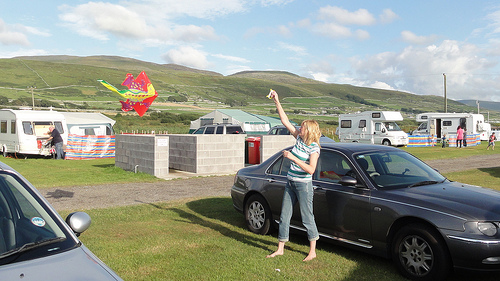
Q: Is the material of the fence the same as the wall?
A: No, the fence is made of plastic and the wall is made of concrete.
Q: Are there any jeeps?
A: No, there are no jeeps.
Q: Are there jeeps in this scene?
A: No, there are no jeeps.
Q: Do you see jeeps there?
A: No, there are no jeeps.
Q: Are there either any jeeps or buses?
A: No, there are no jeeps or buses.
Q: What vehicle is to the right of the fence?
A: The vehicle is a car.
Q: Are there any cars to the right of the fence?
A: Yes, there is a car to the right of the fence.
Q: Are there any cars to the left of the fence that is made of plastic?
A: No, the car is to the right of the fence.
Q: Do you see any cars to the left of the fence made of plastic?
A: No, the car is to the right of the fence.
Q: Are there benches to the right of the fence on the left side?
A: No, there is a car to the right of the fence.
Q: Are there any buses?
A: No, there are no buses.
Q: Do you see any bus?
A: No, there are no buses.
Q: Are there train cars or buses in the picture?
A: No, there are no buses or train cars.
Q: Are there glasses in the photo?
A: No, there are no glasses.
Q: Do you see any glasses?
A: No, there are no glasses.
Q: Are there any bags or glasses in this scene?
A: No, there are no glasses or bags.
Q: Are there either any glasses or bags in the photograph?
A: No, there are no glasses or bags.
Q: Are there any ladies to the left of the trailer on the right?
A: Yes, there is a lady to the left of the trailer.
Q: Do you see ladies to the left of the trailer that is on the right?
A: Yes, there is a lady to the left of the trailer.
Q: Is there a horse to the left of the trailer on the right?
A: No, there is a lady to the left of the trailer.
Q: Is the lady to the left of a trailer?
A: Yes, the lady is to the left of a trailer.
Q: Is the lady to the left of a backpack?
A: No, the lady is to the left of a trailer.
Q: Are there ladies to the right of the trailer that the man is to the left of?
A: Yes, there is a lady to the right of the trailer.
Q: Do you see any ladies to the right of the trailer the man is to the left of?
A: Yes, there is a lady to the right of the trailer.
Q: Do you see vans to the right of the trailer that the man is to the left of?
A: No, there is a lady to the right of the trailer.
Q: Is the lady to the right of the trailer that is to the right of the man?
A: Yes, the lady is to the right of the trailer.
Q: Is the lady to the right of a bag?
A: No, the lady is to the right of the trailer.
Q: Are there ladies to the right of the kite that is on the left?
A: Yes, there is a lady to the right of the kite.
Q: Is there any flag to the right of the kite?
A: No, there is a lady to the right of the kite.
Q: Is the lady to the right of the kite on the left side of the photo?
A: Yes, the lady is to the right of the kite.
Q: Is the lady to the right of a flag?
A: No, the lady is to the right of the kite.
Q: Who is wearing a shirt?
A: The lady is wearing a shirt.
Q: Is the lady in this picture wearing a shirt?
A: Yes, the lady is wearing a shirt.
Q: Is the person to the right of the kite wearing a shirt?
A: Yes, the lady is wearing a shirt.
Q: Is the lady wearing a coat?
A: No, the lady is wearing a shirt.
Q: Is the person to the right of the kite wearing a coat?
A: No, the lady is wearing a shirt.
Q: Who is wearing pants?
A: The lady is wearing pants.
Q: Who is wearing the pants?
A: The lady is wearing pants.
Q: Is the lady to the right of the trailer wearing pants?
A: Yes, the lady is wearing pants.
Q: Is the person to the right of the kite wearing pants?
A: Yes, the lady is wearing pants.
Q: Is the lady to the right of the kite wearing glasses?
A: No, the lady is wearing pants.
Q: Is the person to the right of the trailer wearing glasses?
A: No, the lady is wearing pants.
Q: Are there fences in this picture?
A: Yes, there is a fence.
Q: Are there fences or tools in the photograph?
A: Yes, there is a fence.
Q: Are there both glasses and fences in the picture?
A: No, there is a fence but no glasses.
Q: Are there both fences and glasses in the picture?
A: No, there is a fence but no glasses.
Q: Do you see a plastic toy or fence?
A: Yes, there is a plastic fence.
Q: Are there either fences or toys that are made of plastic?
A: Yes, the fence is made of plastic.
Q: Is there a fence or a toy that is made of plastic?
A: Yes, the fence is made of plastic.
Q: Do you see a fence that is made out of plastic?
A: Yes, there is a fence that is made of plastic.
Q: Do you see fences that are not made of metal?
A: Yes, there is a fence that is made of plastic.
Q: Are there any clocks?
A: No, there are no clocks.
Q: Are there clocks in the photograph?
A: No, there are no clocks.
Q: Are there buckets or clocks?
A: No, there are no clocks or buckets.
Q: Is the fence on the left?
A: Yes, the fence is on the left of the image.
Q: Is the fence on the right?
A: No, the fence is on the left of the image.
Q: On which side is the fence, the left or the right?
A: The fence is on the left of the image.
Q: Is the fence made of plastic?
A: Yes, the fence is made of plastic.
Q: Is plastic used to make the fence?
A: Yes, the fence is made of plastic.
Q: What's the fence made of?
A: The fence is made of plastic.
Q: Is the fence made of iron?
A: No, the fence is made of plastic.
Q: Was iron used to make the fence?
A: No, the fence is made of plastic.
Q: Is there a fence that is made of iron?
A: No, there is a fence but it is made of plastic.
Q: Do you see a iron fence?
A: No, there is a fence but it is made of plastic.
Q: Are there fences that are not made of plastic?
A: No, there is a fence but it is made of plastic.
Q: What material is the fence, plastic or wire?
A: The fence is made of plastic.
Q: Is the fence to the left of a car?
A: Yes, the fence is to the left of a car.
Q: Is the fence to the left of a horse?
A: No, the fence is to the left of a car.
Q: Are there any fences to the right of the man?
A: Yes, there is a fence to the right of the man.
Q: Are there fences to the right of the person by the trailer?
A: Yes, there is a fence to the right of the man.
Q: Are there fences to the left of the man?
A: No, the fence is to the right of the man.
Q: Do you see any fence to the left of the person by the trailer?
A: No, the fence is to the right of the man.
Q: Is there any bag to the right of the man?
A: No, there is a fence to the right of the man.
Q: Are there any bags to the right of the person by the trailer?
A: No, there is a fence to the right of the man.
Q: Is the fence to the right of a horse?
A: No, the fence is to the right of the man.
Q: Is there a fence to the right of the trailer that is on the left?
A: Yes, there is a fence to the right of the trailer.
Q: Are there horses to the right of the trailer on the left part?
A: No, there is a fence to the right of the trailer.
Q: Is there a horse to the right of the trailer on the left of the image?
A: No, there is a fence to the right of the trailer.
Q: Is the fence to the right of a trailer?
A: Yes, the fence is to the right of a trailer.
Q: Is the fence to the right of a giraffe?
A: No, the fence is to the right of a trailer.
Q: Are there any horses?
A: No, there are no horses.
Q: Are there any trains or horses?
A: No, there are no horses or trains.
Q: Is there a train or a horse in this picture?
A: No, there are no horses or trains.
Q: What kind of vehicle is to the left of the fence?
A: The vehicle is a trailer.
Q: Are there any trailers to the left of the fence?
A: Yes, there is a trailer to the left of the fence.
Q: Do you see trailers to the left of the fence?
A: Yes, there is a trailer to the left of the fence.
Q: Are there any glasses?
A: No, there are no glasses.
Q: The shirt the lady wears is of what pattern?
A: The shirt is striped.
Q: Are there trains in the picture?
A: No, there are no trains.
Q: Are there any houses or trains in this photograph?
A: No, there are no trains or houses.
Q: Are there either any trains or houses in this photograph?
A: No, there are no trains or houses.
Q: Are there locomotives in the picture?
A: No, there are no locomotives.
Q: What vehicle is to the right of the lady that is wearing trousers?
A: The vehicle is a trailer.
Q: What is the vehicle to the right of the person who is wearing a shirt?
A: The vehicle is a trailer.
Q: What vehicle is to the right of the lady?
A: The vehicle is a trailer.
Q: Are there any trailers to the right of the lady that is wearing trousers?
A: Yes, there is a trailer to the right of the lady.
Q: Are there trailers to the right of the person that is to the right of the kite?
A: Yes, there is a trailer to the right of the lady.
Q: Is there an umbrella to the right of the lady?
A: No, there is a trailer to the right of the lady.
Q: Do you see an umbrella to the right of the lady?
A: No, there is a trailer to the right of the lady.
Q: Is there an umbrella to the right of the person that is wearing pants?
A: No, there is a trailer to the right of the lady.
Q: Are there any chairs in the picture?
A: No, there are no chairs.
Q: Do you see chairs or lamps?
A: No, there are no chairs or lamps.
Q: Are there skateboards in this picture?
A: No, there are no skateboards.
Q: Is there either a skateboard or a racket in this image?
A: No, there are no skateboards or rackets.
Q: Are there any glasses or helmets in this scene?
A: No, there are no glasses or helmets.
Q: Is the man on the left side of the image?
A: Yes, the man is on the left of the image.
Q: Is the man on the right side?
A: No, the man is on the left of the image.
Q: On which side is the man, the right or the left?
A: The man is on the left of the image.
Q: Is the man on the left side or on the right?
A: The man is on the left of the image.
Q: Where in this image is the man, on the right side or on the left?
A: The man is on the left of the image.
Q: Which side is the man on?
A: The man is on the left of the image.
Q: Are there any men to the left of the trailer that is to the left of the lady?
A: Yes, there is a man to the left of the trailer.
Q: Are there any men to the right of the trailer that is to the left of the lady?
A: No, the man is to the left of the trailer.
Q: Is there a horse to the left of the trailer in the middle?
A: No, there is a man to the left of the trailer.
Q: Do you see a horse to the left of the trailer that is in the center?
A: No, there is a man to the left of the trailer.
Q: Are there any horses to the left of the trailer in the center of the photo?
A: No, there is a man to the left of the trailer.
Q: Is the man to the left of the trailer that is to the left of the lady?
A: Yes, the man is to the left of the trailer.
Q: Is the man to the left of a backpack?
A: No, the man is to the left of the trailer.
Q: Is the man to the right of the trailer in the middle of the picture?
A: No, the man is to the left of the trailer.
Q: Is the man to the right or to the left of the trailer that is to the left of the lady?
A: The man is to the left of the trailer.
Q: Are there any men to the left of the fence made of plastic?
A: Yes, there is a man to the left of the fence.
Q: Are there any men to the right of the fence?
A: No, the man is to the left of the fence.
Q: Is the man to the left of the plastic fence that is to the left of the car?
A: Yes, the man is to the left of the fence.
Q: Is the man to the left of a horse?
A: No, the man is to the left of the fence.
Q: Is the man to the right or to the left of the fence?
A: The man is to the left of the fence.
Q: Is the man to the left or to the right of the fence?
A: The man is to the left of the fence.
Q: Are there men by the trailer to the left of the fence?
A: Yes, there is a man by the trailer.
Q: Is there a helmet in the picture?
A: No, there are no helmets.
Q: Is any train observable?
A: No, there are no trains.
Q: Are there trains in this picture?
A: No, there are no trains.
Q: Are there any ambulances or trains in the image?
A: No, there are no trains or ambulances.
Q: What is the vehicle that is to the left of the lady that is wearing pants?
A: The vehicle is a trailer.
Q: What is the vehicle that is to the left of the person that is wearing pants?
A: The vehicle is a trailer.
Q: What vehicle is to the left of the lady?
A: The vehicle is a trailer.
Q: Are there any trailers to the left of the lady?
A: Yes, there is a trailer to the left of the lady.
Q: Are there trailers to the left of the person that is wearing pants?
A: Yes, there is a trailer to the left of the lady.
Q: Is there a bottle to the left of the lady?
A: No, there is a trailer to the left of the lady.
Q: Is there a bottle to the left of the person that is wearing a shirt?
A: No, there is a trailer to the left of the lady.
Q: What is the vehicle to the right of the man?
A: The vehicle is a trailer.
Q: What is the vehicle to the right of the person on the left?
A: The vehicle is a trailer.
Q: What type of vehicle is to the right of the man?
A: The vehicle is a trailer.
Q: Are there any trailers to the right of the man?
A: Yes, there is a trailer to the right of the man.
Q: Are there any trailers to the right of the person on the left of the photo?
A: Yes, there is a trailer to the right of the man.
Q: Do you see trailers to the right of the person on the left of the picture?
A: Yes, there is a trailer to the right of the man.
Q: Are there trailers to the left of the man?
A: No, the trailer is to the right of the man.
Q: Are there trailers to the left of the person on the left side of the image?
A: No, the trailer is to the right of the man.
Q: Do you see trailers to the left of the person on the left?
A: No, the trailer is to the right of the man.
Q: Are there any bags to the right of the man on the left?
A: No, there is a trailer to the right of the man.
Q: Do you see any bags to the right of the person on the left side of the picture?
A: No, there is a trailer to the right of the man.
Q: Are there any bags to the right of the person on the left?
A: No, there is a trailer to the right of the man.